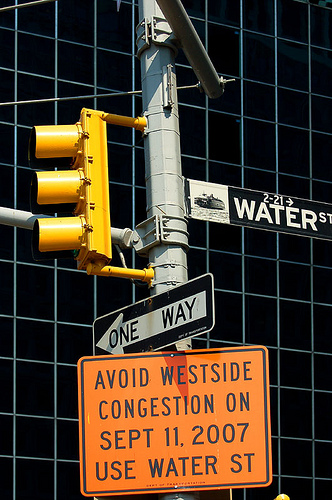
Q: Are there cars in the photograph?
A: No, there are no cars.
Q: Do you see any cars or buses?
A: No, there are no cars or buses.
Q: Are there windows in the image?
A: Yes, there is a window.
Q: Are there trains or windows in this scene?
A: Yes, there is a window.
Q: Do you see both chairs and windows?
A: No, there is a window but no chairs.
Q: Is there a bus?
A: No, there are no buses.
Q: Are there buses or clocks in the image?
A: No, there are no buses or clocks.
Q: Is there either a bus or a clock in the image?
A: No, there are no buses or clocks.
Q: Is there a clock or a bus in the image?
A: No, there are no buses or clocks.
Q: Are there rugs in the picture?
A: No, there are no rugs.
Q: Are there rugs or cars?
A: No, there are no rugs or cars.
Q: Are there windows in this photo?
A: Yes, there is a window.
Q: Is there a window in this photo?
A: Yes, there is a window.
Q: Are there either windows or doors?
A: Yes, there is a window.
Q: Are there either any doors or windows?
A: Yes, there is a window.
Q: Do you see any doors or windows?
A: Yes, there is a window.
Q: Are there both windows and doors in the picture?
A: No, there is a window but no doors.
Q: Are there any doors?
A: No, there are no doors.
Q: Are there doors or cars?
A: No, there are no doors or cars.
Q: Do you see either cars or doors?
A: No, there are no doors or cars.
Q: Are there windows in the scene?
A: Yes, there is a window.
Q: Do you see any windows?
A: Yes, there is a window.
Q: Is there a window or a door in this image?
A: Yes, there is a window.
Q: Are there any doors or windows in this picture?
A: Yes, there is a window.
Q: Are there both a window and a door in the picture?
A: No, there is a window but no doors.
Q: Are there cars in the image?
A: No, there are no cars.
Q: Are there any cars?
A: No, there are no cars.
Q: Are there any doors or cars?
A: No, there are no cars or doors.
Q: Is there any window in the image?
A: Yes, there is a window.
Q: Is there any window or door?
A: Yes, there is a window.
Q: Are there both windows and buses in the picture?
A: No, there is a window but no buses.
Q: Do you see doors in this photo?
A: No, there are no doors.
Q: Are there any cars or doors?
A: No, there are no doors or cars.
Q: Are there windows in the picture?
A: Yes, there is a window.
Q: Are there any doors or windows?
A: Yes, there is a window.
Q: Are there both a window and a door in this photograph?
A: No, there is a window but no doors.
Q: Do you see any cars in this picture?
A: No, there are no cars.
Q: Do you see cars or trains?
A: No, there are no cars or trains.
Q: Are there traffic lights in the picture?
A: Yes, there is a traffic light.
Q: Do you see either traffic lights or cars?
A: Yes, there is a traffic light.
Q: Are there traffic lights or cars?
A: Yes, there is a traffic light.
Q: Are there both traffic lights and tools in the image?
A: No, there is a traffic light but no tools.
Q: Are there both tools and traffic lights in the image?
A: No, there is a traffic light but no tools.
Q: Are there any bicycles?
A: No, there are no bicycles.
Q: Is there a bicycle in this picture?
A: No, there are no bicycles.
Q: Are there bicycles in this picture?
A: No, there are no bicycles.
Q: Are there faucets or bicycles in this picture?
A: No, there are no bicycles or faucets.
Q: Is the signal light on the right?
A: No, the signal light is on the left of the image.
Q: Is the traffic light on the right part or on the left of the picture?
A: The traffic light is on the left of the image.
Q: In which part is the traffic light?
A: The traffic light is on the left of the image.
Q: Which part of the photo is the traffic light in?
A: The traffic light is on the left of the image.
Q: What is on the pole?
A: The traffic light is on the pole.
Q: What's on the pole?
A: The traffic light is on the pole.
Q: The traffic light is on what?
A: The traffic light is on the pole.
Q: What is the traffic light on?
A: The traffic light is on the pole.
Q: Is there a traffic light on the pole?
A: Yes, there is a traffic light on the pole.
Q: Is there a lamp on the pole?
A: No, there is a traffic light on the pole.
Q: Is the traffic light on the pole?
A: Yes, the traffic light is on the pole.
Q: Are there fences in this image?
A: No, there are no fences.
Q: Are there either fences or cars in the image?
A: No, there are no fences or cars.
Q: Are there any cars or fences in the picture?
A: No, there are no fences or cars.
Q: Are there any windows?
A: Yes, there is a window.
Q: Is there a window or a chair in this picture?
A: Yes, there is a window.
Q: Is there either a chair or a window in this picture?
A: Yes, there is a window.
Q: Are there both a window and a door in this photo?
A: No, there is a window but no doors.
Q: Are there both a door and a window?
A: No, there is a window but no doors.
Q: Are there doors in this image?
A: No, there are no doors.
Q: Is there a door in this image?
A: No, there are no doors.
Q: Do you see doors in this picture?
A: No, there are no doors.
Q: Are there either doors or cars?
A: No, there are no doors or cars.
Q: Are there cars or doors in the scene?
A: No, there are no doors or cars.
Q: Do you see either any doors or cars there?
A: No, there are no doors or cars.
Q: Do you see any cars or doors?
A: No, there are no doors or cars.